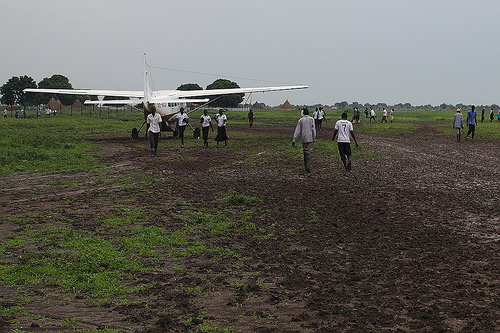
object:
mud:
[104, 124, 500, 332]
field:
[0, 111, 497, 331]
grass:
[1, 112, 499, 281]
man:
[331, 112, 360, 172]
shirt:
[334, 119, 354, 143]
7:
[342, 124, 347, 132]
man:
[290, 107, 319, 174]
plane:
[22, 51, 310, 140]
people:
[175, 106, 189, 147]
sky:
[1, 0, 498, 106]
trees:
[1, 75, 40, 115]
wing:
[22, 86, 144, 99]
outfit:
[452, 112, 464, 134]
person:
[453, 107, 464, 141]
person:
[144, 107, 164, 154]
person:
[464, 105, 477, 140]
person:
[247, 109, 255, 127]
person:
[387, 109, 395, 123]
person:
[316, 106, 327, 132]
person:
[369, 108, 378, 123]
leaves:
[59, 80, 63, 85]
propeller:
[186, 97, 196, 110]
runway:
[0, 113, 272, 281]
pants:
[148, 132, 160, 149]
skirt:
[214, 125, 229, 142]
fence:
[0, 104, 142, 118]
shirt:
[467, 110, 477, 125]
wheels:
[132, 128, 139, 140]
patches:
[15, 195, 257, 295]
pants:
[301, 142, 314, 167]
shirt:
[292, 115, 317, 144]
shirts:
[200, 115, 212, 128]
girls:
[214, 109, 230, 148]